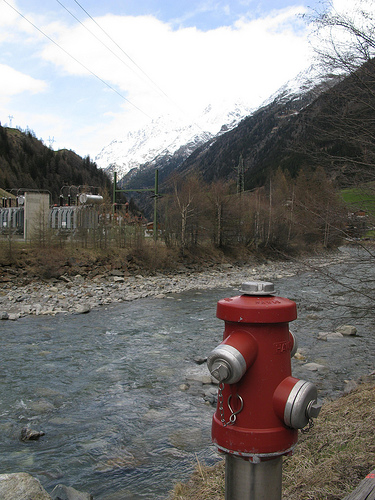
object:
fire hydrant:
[206, 281, 322, 500]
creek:
[0, 246, 374, 499]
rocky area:
[0, 252, 351, 320]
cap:
[238, 281, 277, 296]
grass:
[165, 375, 374, 499]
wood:
[339, 469, 375, 500]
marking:
[364, 472, 374, 479]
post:
[153, 169, 159, 242]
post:
[111, 172, 117, 214]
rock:
[317, 330, 344, 341]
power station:
[0, 168, 158, 240]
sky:
[0, 0, 374, 161]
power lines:
[0, 0, 205, 133]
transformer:
[51, 185, 105, 241]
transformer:
[0, 187, 53, 239]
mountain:
[129, 49, 365, 221]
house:
[141, 219, 166, 237]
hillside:
[0, 126, 161, 224]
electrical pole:
[7, 114, 15, 128]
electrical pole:
[46, 135, 57, 150]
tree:
[268, 0, 374, 350]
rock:
[335, 324, 357, 336]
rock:
[301, 362, 327, 372]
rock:
[193, 355, 208, 364]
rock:
[186, 373, 220, 385]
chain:
[217, 381, 244, 426]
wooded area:
[0, 167, 352, 283]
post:
[225, 454, 283, 500]